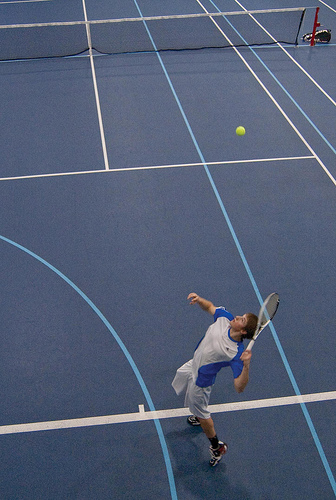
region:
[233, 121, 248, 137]
a yellow tennis ball in the air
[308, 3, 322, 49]
a red post holding a tennis net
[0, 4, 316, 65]
a tennis net on a tennis court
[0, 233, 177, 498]
a blue curving line on a tennis court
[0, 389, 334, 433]
a white line on a tennis court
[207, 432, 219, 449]
a black sock on a man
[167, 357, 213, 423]
grey shorts on a man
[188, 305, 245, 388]
a blue and grey shirt on a man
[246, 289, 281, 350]
a black and white tennis racket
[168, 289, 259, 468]
a man playing tennis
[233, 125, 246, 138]
a bright yellow tennis ball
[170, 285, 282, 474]
a tennis player hitting a ball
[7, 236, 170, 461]
lines on the floor of a tennis court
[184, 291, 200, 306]
the hand of a man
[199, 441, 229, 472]
the foot of a man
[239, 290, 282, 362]
a tennis racquet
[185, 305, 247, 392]
a blue and white tennis jersey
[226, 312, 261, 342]
the head of a man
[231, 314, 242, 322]
the nose of a man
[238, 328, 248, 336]
the ear of a man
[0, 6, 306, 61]
the tennis court's net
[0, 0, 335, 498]
a tennis court surface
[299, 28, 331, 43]
a bag on the tennis court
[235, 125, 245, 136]
a tennis ball in flight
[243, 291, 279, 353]
a tennis racket held by the man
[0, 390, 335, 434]
a white line on the tennis court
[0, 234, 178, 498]
a blue line on the tennis court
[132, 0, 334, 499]
a blue line on the tennis court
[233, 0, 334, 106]
a white line on the tennis court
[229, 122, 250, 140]
the green tennis ball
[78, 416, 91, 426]
a white line on the tennis court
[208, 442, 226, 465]
his white and red shoes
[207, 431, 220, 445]
his black socks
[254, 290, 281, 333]
the tennis player's tennis racket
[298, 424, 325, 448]
a blue line on the court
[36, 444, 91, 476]
the blue tennis court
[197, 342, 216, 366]
the tennis player's white shirt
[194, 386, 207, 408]
the tennis players white shorts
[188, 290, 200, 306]
the tennis player's hand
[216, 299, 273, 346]
the head of a man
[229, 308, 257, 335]
the eyes of a man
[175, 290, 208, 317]
the hand of a man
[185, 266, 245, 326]
the arm of a man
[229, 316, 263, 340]
the ear of a man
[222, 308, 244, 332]
the nose of a man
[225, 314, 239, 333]
the mouth of a man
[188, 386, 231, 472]
the leg of a man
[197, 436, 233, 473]
the foot of a man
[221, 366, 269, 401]
the elbow of a man